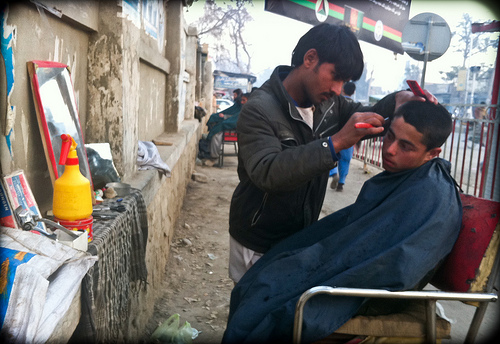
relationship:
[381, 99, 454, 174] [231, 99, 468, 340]
head belonging to boy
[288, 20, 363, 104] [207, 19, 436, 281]
head belonging to barber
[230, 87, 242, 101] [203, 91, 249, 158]
head belonging to kid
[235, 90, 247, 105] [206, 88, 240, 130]
head belonging to kid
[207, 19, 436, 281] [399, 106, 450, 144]
barber cuts hair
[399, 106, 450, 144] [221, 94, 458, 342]
hair on boy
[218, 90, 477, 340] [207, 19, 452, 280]
boy visits barber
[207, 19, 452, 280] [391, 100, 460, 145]
barber cuts hair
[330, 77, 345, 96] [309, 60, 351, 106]
nose on face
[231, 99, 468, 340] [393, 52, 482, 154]
boy in front of giraffe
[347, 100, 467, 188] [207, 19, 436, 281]
head of barber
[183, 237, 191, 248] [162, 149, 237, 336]
rock on ground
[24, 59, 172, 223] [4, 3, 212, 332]
mirror next to wall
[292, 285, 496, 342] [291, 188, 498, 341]
arm of chair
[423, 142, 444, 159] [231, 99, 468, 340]
ear of boy